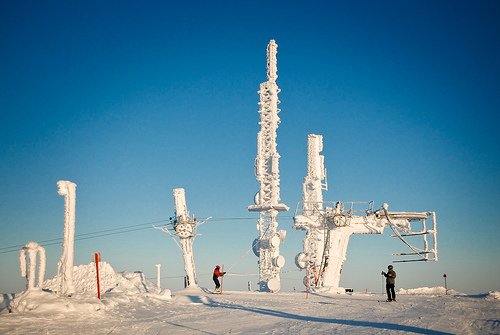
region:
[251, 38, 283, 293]
A communication satellite tower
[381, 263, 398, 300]
A man in all black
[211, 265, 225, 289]
A man in black and red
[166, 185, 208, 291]
A white utility pole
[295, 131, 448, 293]
Frozen utility pole equiptment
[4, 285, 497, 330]
Snow falling on ground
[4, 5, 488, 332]
A clear winter day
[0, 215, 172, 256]
A power line running overhead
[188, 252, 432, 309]
People skiing out doors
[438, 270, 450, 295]
A small sign pole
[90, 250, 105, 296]
The red pole on the left.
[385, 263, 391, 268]
The black helmet the person on the right is wearing.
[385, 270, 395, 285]
The coat the person on the right is wearing.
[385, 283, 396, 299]
The pants the person on the right is wearing.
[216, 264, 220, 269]
The red hat the person on the left is wearing.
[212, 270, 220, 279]
The red and black coat the person is wearing.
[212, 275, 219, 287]
The pants the person on the right is wearing.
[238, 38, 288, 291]
The tall snowy structure.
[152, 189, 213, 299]
The structure behind the person in red.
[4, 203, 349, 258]
The wires in the air connected to the structures.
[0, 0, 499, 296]
a large patch of blue sky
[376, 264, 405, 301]
a person skiing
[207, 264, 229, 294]
a person skiing in a red jacket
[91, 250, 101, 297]
a red signpost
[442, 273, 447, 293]
a small post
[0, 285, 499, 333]
a snow covered ground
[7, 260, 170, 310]
a pile of snow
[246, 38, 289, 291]
a radio tower covered in ice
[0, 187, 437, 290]
a ski chair lift covered in ice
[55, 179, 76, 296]
a light pole covered in ice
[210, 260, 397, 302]
the people are skiing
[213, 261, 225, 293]
the person is wearing red and black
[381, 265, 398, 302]
the person is wearing a black outfit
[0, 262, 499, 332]
the ground is full of snow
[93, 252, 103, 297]
the pole is red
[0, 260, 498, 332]
the people are standing on the snow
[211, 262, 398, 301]
two people are skiing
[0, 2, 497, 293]
the sky has gradient color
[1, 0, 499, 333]
the scene takes place outdoors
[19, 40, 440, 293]
the objects are white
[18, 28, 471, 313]
photograph taken in the winter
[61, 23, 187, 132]
clear blue sky with no clouds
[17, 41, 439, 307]
items covered with snow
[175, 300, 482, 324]
white snow covering the ground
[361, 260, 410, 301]
person skiing by snow covered items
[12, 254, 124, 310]
pile of white snow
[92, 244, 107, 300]
orange pole with a sign on it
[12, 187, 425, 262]
electrical wires in the air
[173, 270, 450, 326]
shadow on the ground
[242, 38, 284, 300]
tall tower covered with snow